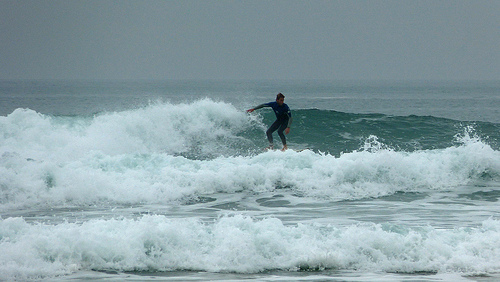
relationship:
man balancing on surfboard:
[243, 84, 291, 152] [262, 142, 291, 157]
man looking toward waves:
[243, 84, 291, 152] [1, 92, 499, 279]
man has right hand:
[243, 84, 291, 152] [245, 104, 256, 116]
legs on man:
[262, 118, 289, 148] [243, 84, 291, 152]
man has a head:
[243, 84, 291, 152] [274, 90, 287, 105]